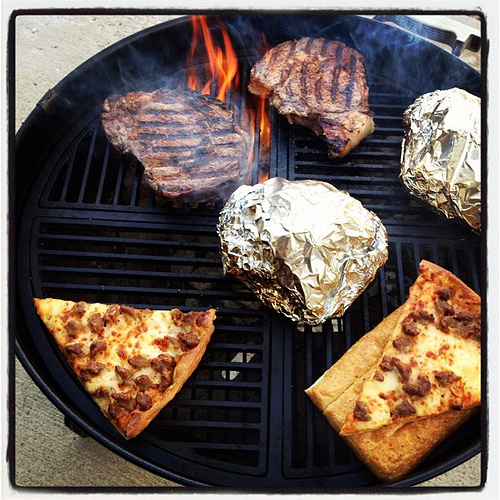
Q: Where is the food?
A: On the grill.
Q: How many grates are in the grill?
A: Four.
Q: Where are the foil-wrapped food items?
A: On the grill in the center and between the meat and pizza.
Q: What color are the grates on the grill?
A: Black.